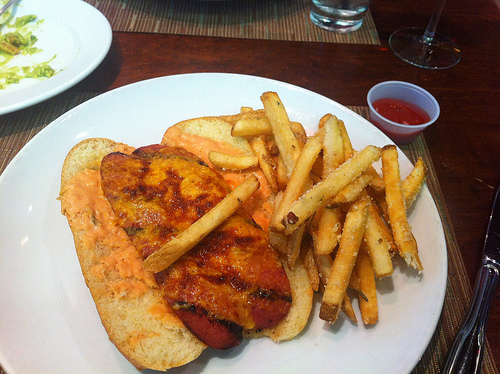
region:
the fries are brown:
[237, 116, 418, 296]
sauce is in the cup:
[375, 96, 417, 121]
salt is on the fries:
[263, 143, 364, 243]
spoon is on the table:
[466, 246, 497, 371]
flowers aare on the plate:
[0, 15, 80, 93]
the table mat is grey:
[176, 13, 291, 38]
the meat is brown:
[105, 147, 291, 337]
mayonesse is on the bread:
[77, 208, 128, 284]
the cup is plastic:
[365, 82, 445, 132]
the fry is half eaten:
[392, 188, 420, 268]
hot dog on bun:
[58, 115, 314, 371]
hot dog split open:
[101, 143, 296, 341]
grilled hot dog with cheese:
[102, 148, 294, 345]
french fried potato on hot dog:
[141, 175, 263, 290]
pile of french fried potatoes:
[233, 89, 429, 341]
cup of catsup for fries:
[368, 78, 444, 141]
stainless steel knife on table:
[437, 189, 495, 372]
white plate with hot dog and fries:
[6, 71, 445, 372]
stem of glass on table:
[385, 1, 462, 70]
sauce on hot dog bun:
[68, 169, 159, 304]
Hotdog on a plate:
[10, 60, 300, 370]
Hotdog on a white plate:
[55, 120, 300, 360]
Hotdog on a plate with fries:
[61, 80, 406, 330]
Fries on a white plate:
[314, 140, 434, 317]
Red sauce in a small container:
[357, 63, 439, 133]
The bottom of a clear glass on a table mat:
[301, 0, 373, 40]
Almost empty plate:
[15, 0, 126, 81]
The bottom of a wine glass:
[386, 5, 461, 73]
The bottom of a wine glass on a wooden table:
[385, 8, 480, 71]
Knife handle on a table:
[447, 219, 499, 366]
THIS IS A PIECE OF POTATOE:
[147, 184, 251, 286]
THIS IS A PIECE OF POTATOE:
[294, 263, 309, 325]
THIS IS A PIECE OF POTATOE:
[321, 221, 363, 290]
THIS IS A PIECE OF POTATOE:
[394, 165, 405, 238]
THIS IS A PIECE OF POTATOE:
[295, 172, 369, 193]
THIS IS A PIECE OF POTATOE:
[274, 103, 291, 146]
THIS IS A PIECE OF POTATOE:
[234, 108, 266, 139]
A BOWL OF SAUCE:
[376, 84, 434, 139]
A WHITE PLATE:
[13, 245, 39, 307]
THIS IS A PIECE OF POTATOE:
[106, 255, 116, 335]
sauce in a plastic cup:
[364, 70, 444, 140]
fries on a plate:
[225, 100, 447, 330]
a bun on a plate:
[60, 113, 321, 368]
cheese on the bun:
[70, 151, 135, 300]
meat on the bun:
[103, 132, 295, 355]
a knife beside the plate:
[437, 178, 498, 368]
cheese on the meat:
[115, 144, 287, 322]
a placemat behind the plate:
[78, 0, 393, 60]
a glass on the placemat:
[308, 1, 369, 38]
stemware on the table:
[382, 2, 471, 82]